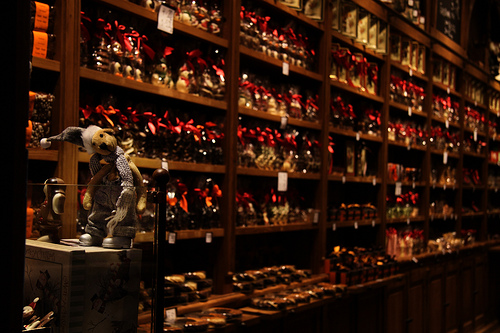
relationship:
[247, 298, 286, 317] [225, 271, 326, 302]
toy car on shelf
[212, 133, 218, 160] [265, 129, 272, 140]
items on redribbon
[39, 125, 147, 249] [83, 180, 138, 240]
animal on pants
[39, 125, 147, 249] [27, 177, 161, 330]
animal on glass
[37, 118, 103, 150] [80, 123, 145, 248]
hat on bear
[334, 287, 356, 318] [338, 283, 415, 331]
knob on cabinet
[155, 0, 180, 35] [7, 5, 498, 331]
paper on shelf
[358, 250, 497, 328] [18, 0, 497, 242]
cabinets on shelves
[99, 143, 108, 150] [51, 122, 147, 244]
black nose on dog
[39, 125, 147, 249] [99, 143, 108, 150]
animal has black nose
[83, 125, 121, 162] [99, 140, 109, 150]
dog face has black nose